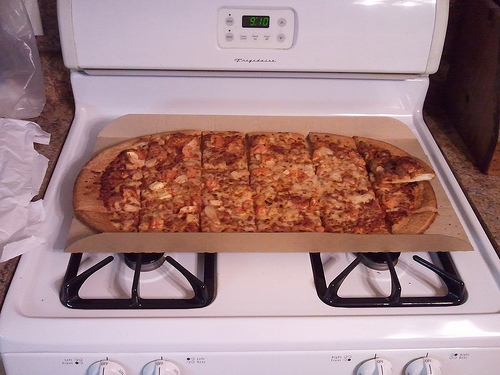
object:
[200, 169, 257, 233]
pizza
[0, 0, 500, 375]
gas stove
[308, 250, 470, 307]
burner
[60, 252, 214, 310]
burner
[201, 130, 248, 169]
slice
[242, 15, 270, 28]
digital clock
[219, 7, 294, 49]
buttons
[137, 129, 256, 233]
squares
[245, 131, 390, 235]
squares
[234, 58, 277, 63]
logo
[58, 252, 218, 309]
stove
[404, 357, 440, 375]
burner knob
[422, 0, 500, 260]
countertop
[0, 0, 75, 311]
countertop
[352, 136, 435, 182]
pizza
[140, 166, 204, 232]
pizza slice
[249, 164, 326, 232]
pizza slice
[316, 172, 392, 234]
pizza slice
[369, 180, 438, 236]
pizza slice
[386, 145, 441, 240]
crust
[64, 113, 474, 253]
cardboard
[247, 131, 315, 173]
slice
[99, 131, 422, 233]
sauce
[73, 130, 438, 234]
cheese